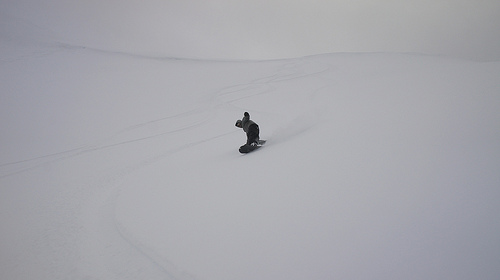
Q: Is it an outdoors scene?
A: Yes, it is outdoors.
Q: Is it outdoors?
A: Yes, it is outdoors.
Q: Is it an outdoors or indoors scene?
A: It is outdoors.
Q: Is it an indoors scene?
A: No, it is outdoors.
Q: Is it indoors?
A: No, it is outdoors.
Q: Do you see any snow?
A: Yes, there is snow.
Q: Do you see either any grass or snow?
A: Yes, there is snow.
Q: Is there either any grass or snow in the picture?
A: Yes, there is snow.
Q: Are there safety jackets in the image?
A: No, there are no safety jackets.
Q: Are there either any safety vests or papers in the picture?
A: No, there are no safety vests or papers.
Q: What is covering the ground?
A: The snow is covering the ground.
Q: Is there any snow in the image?
A: Yes, there is snow.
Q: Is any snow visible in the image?
A: Yes, there is snow.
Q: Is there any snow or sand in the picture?
A: Yes, there is snow.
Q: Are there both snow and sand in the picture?
A: No, there is snow but no sand.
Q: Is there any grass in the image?
A: No, there is no grass.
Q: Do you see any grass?
A: No, there is no grass.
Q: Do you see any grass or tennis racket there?
A: No, there are no grass or rackets.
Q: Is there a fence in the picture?
A: No, there are no fences.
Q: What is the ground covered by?
A: The ground is covered by the snow.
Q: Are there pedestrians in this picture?
A: No, there are no pedestrians.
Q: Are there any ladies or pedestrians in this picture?
A: No, there are no pedestrians or ladies.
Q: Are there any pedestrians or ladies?
A: No, there are no pedestrians or ladies.